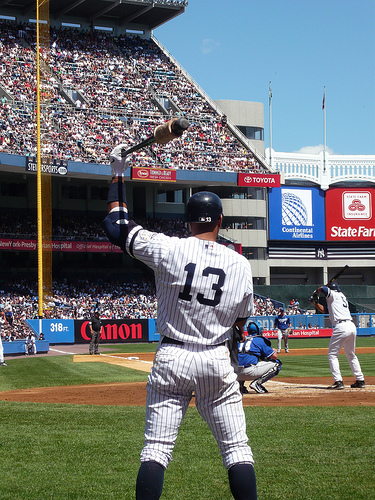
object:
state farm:
[324, 182, 374, 245]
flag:
[321, 86, 324, 110]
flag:
[268, 81, 272, 102]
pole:
[321, 87, 326, 173]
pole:
[268, 80, 273, 165]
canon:
[74, 318, 150, 346]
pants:
[237, 359, 280, 382]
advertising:
[75, 319, 148, 343]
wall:
[33, 311, 372, 345]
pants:
[327, 322, 366, 381]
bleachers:
[0, 0, 280, 188]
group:
[0, 214, 307, 340]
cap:
[185, 191, 224, 224]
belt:
[159, 334, 229, 347]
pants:
[134, 339, 256, 498]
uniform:
[104, 206, 256, 500]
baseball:
[178, 189, 224, 226]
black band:
[105, 180, 127, 203]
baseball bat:
[308, 265, 349, 303]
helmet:
[328, 281, 341, 291]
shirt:
[103, 206, 254, 349]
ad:
[268, 187, 324, 241]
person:
[75, 99, 82, 107]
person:
[81, 101, 89, 109]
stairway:
[61, 88, 92, 109]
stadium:
[1, 0, 374, 499]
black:
[227, 463, 257, 500]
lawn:
[259, 415, 372, 498]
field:
[1, 322, 373, 498]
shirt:
[88, 317, 102, 332]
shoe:
[350, 380, 366, 389]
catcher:
[236, 322, 282, 394]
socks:
[135, 462, 163, 500]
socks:
[227, 463, 258, 499]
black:
[135, 461, 163, 500]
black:
[183, 191, 224, 225]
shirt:
[274, 315, 291, 331]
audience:
[0, 29, 272, 175]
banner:
[132, 168, 177, 182]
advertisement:
[239, 172, 280, 186]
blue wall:
[25, 318, 164, 342]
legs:
[135, 345, 258, 499]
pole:
[35, 0, 44, 320]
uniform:
[309, 285, 365, 383]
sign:
[326, 188, 374, 241]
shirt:
[232, 334, 274, 368]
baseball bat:
[118, 118, 190, 158]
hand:
[109, 143, 132, 173]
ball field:
[2, 318, 374, 497]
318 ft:
[50, 322, 69, 332]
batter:
[103, 143, 256, 499]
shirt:
[320, 286, 354, 325]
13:
[178, 261, 226, 307]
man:
[308, 284, 366, 389]